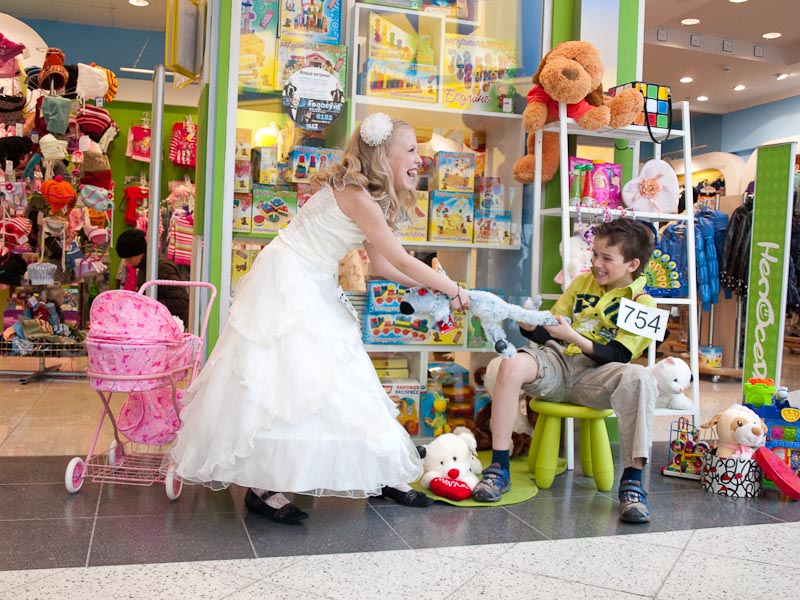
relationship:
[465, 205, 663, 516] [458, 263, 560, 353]
kid tugging on animal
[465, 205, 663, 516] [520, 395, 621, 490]
kid sitting on stool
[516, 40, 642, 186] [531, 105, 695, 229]
dog on shelf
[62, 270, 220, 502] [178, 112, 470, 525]
baby carriage next to girl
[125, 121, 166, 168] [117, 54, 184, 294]
shirts hanging on racks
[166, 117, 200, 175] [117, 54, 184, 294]
shirts hanging on racks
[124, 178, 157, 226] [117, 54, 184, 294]
shirts hanging on racks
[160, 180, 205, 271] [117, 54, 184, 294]
shirts hanging on racks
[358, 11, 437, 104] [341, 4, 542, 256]
toys are on shelf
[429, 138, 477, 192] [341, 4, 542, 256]
toys are on shelf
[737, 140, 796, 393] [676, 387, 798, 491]
sign on ground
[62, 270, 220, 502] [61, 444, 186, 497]
baby carriage with wheels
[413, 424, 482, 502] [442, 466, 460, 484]
stuffed animal with red nose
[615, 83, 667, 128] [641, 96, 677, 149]
rubik cube with black strap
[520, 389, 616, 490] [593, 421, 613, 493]
green stool with leg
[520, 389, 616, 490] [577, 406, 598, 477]
green stool with leg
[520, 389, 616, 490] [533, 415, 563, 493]
green stool with leg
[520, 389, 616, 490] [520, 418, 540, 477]
green stool with leg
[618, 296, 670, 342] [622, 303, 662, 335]
white card with number 754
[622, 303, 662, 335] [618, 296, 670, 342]
number 754 on white card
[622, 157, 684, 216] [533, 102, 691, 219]
box on shelf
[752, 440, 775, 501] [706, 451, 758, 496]
red top belonging to box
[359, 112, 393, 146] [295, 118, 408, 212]
white bow in hair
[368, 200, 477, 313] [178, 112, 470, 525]
arm of girl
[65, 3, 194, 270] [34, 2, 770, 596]
wall on side of building